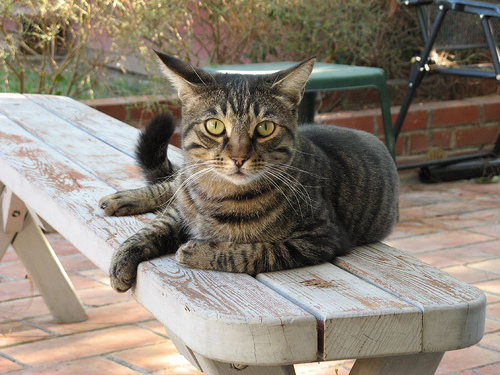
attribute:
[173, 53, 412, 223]
table — green, plastic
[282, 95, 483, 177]
wall — brick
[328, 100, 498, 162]
wall — brick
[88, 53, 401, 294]
cat — grey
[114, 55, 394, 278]
cat — gray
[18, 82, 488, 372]
bench — wooden, grey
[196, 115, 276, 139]
eyes — yellow, feline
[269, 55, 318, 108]
ear — feline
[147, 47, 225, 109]
ear — feline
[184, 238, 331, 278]
leg — feline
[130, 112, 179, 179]
tail — feline, black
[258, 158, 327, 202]
whiskers — feline, white 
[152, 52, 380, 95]
table — green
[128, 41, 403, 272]
cat — grey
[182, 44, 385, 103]
table — green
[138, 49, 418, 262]
cat — grey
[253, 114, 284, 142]
eye — yellow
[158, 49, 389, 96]
table — green, plastic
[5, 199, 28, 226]
bolt — metal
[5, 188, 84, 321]
legs — bench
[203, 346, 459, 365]
legs — bench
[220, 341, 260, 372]
bolt — metal